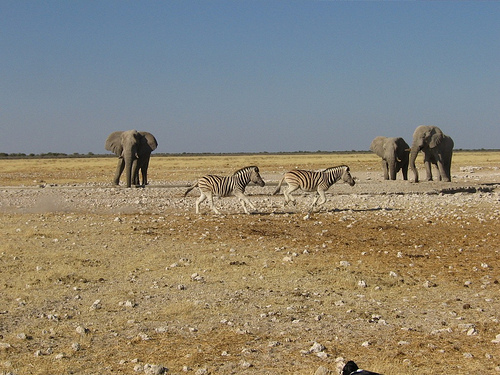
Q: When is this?
A: Daytime.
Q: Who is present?
A: No one.